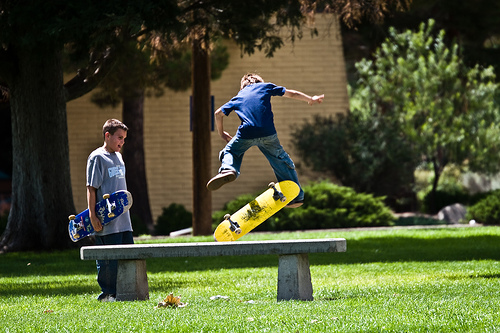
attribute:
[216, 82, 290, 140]
shirt — blue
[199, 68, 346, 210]
boy — doing, wearing, skateboarding, little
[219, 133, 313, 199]
jeans — blue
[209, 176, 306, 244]
skateboard — yellow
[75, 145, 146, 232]
shirt — gray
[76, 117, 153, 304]
boy — watching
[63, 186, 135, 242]
skateboard — blue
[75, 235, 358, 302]
bench — concrete, cement, stone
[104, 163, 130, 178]
letters — blue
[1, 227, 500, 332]
grass — green, grassy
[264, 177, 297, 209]
wheels — white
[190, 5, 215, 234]
pole — wooden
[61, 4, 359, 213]
building — brick, tan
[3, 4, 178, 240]
tree — growing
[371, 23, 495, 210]
tree — growing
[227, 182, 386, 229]
bushes — growing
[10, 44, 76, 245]
trunk — thick, brown